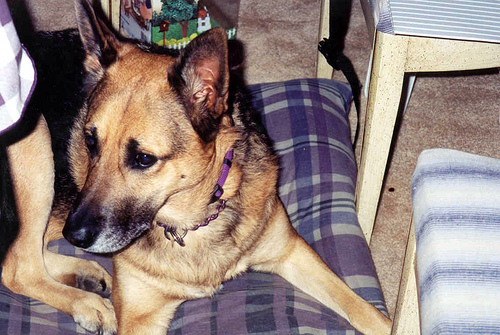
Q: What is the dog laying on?
A: His pillow.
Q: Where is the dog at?
A: In his home.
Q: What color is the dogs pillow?
A: Purple and blue plaid.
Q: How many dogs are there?
A: One.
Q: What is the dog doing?
A: Laying down.